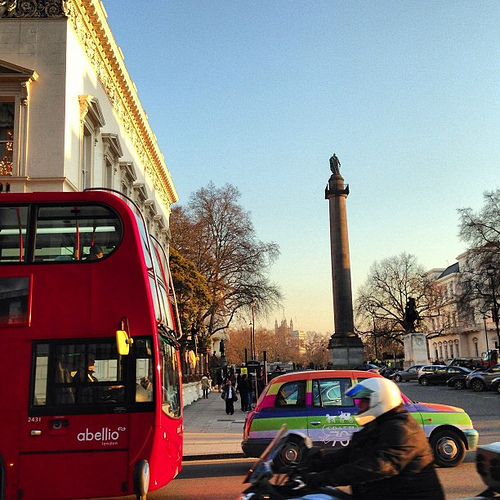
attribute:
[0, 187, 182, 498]
bus — red, two story, a double decker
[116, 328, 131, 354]
mirror — side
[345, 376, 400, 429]
helmet — white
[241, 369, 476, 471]
car — multi colored, brightly colored, white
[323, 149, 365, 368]
monument — tall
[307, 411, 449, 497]
coat — brown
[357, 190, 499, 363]
trees — leafless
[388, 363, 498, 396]
cars — parked